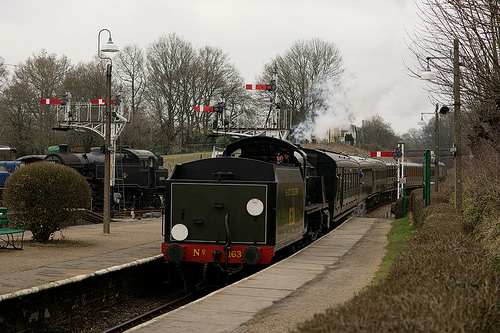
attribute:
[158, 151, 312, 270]
car — black and red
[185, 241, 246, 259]
writing — yellow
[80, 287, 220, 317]
track — metal, train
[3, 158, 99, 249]
bush — trimmed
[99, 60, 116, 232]
post — wooden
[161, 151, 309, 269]
engine — small, black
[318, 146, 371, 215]
car — black, passenger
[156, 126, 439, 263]
train — passenger, black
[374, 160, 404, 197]
car — black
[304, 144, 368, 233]
passenger car — black train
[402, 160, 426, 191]
passenger car — black train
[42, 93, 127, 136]
traffic signal — a railroad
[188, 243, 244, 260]
train no — printed, 163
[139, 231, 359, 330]
sidewalk — gray cement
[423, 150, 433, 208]
post — green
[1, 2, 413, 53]
sky — grey overcast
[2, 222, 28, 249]
bench — green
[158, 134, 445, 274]
train — black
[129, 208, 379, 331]
sidewalk — cement